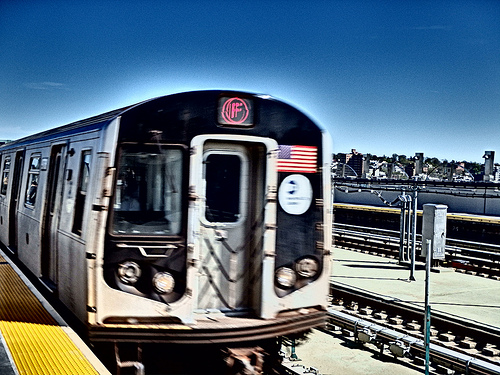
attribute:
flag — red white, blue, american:
[277, 143, 321, 173]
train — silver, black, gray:
[1, 89, 332, 348]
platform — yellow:
[1, 248, 114, 374]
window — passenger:
[68, 147, 94, 239]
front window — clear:
[105, 139, 187, 240]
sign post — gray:
[420, 236, 435, 345]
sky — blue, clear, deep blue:
[1, 1, 500, 166]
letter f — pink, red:
[231, 103, 243, 120]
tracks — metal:
[323, 280, 499, 375]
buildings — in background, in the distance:
[337, 153, 365, 178]